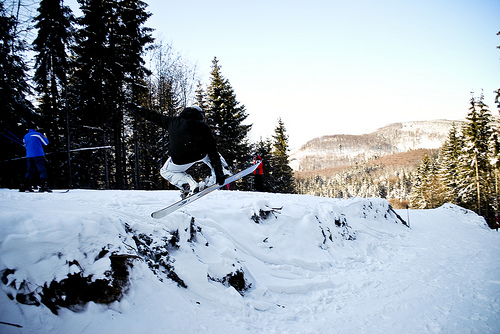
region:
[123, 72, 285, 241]
a person snowboarding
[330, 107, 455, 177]
a mountain covered in snow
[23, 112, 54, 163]
a person wearing a blue jacket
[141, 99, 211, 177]
a person wearing a black coat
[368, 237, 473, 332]
snow covering the ground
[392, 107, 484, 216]
several trees covered with snow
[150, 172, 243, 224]
a white snow board in the air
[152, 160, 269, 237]
a white snow board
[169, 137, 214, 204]
a person wearing white pants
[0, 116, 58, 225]
a man standing a snowboard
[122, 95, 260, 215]
young man in air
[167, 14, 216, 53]
white clouds in blue sky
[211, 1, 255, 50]
white clouds in blue sky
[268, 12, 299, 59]
white clouds in blue sky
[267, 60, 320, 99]
white clouds in blue sky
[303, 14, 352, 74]
white clouds in blue sky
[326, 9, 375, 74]
white clouds in blue sky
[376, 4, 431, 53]
white clouds in blue sky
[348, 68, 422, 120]
white clouds in blue sky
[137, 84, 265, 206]
person doing trick on snowboard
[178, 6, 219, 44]
white clouds in blue sky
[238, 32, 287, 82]
white clouds in blue sky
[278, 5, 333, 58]
white clouds in blue sky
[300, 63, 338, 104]
white clouds in blue sky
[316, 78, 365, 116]
white clouds in blue sky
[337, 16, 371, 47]
white clouds in blue sky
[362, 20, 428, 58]
white clouds in blue sky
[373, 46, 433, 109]
white clouds in blue sky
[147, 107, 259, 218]
person in black sweater on snowboard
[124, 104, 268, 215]
man on snowboard jumping slope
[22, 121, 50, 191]
man in blue coat standing besides trees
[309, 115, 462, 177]
hills in the distance with snow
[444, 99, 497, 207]
green trees to the right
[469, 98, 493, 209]
green trees with snow on them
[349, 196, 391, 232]
snow covered rocky slope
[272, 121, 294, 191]
sunlight shinning on green tree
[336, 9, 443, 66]
clear blue sky over hills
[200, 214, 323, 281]
snowboard tracks in the deep snow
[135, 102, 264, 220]
Athletic person on snowboard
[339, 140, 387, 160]
Distant snowy far hill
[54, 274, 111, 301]
Snow covered rock on slope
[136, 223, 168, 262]
Snow covered rock on slope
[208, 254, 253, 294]
Snow covered rock on slope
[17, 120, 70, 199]
Snowboard person in blue jacket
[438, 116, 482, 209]
Snow covered evergreen tree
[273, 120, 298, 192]
Tall evergreen tree on hill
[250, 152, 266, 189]
Snowboard person in red jacket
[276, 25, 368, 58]
Cold blue winter sky